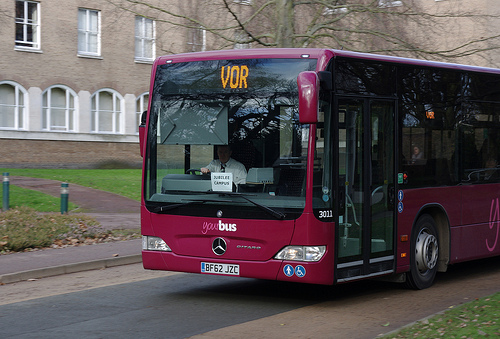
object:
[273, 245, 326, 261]
light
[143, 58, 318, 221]
windshield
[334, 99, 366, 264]
bus door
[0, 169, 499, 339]
ground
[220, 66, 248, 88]
bus sign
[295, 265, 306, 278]
stickers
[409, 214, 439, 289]
tire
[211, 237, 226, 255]
logo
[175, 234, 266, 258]
logo plate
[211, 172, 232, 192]
white sign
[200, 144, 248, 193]
bus driver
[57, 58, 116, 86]
brick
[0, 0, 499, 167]
building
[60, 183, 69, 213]
green light-post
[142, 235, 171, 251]
headlights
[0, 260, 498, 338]
road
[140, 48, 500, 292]
bus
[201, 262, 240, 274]
license plate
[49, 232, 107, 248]
leaves